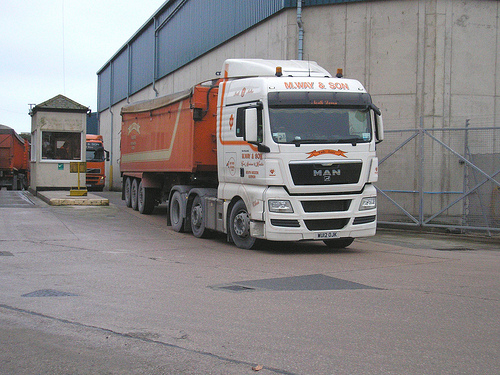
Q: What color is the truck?
A: White and orange.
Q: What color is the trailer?
A: Orange and tan.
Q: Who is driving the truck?
A: The truck driver.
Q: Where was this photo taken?
A: At a loading place.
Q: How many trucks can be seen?
A: Two.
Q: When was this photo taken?
A: During the day.